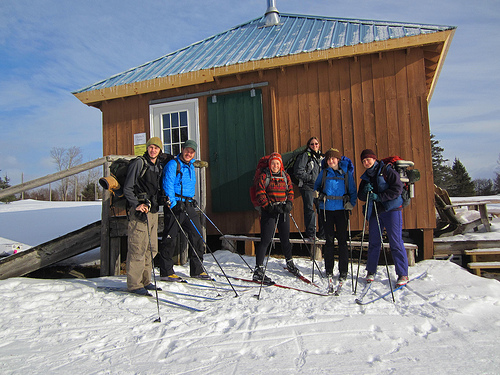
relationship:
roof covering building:
[71, 0, 457, 104] [72, 0, 457, 276]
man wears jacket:
[123, 136, 169, 296] [115, 151, 167, 221]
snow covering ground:
[4, 199, 497, 373] [1, 194, 499, 373]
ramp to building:
[7, 220, 90, 293] [76, 12, 468, 264]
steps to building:
[448, 233, 482, 272] [76, 12, 468, 264]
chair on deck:
[434, 184, 482, 231] [443, 230, 484, 257]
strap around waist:
[318, 196, 348, 202] [320, 180, 347, 215]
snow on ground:
[0, 196, 499, 374] [180, 325, 290, 375]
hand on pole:
[275, 206, 285, 217] [258, 205, 308, 286]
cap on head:
[362, 148, 374, 157] [361, 150, 373, 165]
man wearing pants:
[108, 149, 174, 298] [124, 202, 164, 300]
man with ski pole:
[123, 136, 169, 296] [144, 213, 162, 322]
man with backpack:
[123, 136, 169, 296] [100, 147, 133, 202]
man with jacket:
[160, 138, 212, 279] [163, 153, 195, 209]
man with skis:
[357, 148, 409, 286] [251, 237, 414, 303]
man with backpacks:
[357, 148, 409, 286] [252, 138, 422, 196]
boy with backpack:
[252, 153, 300, 285] [252, 160, 273, 200]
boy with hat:
[252, 153, 300, 285] [267, 151, 284, 162]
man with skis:
[123, 136, 169, 296] [142, 258, 402, 306]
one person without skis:
[293, 129, 321, 220] [142, 258, 402, 306]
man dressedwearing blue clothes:
[357, 148, 409, 286] [364, 172, 402, 251]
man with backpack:
[357, 148, 409, 286] [380, 151, 414, 194]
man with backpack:
[357, 148, 409, 286] [378, 153, 420, 187]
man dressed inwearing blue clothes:
[357, 148, 409, 286] [360, 170, 406, 253]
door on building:
[146, 106, 198, 154] [76, 0, 451, 248]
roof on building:
[60, 0, 450, 107] [76, 0, 451, 248]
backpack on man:
[92, 160, 133, 190] [123, 136, 169, 296]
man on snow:
[123, 136, 169, 296] [190, 283, 440, 350]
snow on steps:
[470, 245, 486, 264] [466, 240, 493, 279]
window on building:
[147, 95, 191, 148] [116, 49, 426, 234]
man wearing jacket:
[160, 138, 212, 279] [167, 156, 207, 199]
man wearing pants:
[160, 138, 212, 279] [178, 212, 219, 262]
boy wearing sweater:
[246, 148, 310, 272] [266, 178, 293, 206]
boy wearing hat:
[252, 153, 300, 285] [262, 145, 288, 166]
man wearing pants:
[357, 148, 409, 286] [363, 210, 417, 270]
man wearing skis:
[357, 148, 409, 286] [346, 278, 423, 306]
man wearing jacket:
[123, 136, 169, 296] [124, 157, 167, 218]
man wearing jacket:
[123, 136, 169, 296] [123, 153, 167, 212]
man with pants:
[123, 136, 169, 296] [127, 208, 157, 298]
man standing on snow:
[160, 138, 212, 279] [7, 251, 497, 371]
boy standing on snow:
[252, 153, 300, 285] [7, 251, 497, 371]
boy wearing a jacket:
[252, 153, 300, 285] [256, 169, 294, 207]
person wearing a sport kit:
[315, 149, 354, 274] [310, 149, 360, 301]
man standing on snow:
[357, 148, 417, 288] [7, 251, 497, 371]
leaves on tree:
[450, 157, 470, 192] [450, 156, 469, 191]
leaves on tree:
[81, 180, 97, 194] [79, 176, 98, 199]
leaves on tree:
[453, 168, 470, 186] [449, 160, 471, 195]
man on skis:
[123, 136, 169, 296] [70, 269, 212, 309]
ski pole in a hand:
[139, 213, 163, 324] [132, 205, 152, 216]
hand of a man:
[132, 205, 152, 216] [123, 136, 169, 296]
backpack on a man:
[106, 156, 133, 207] [128, 138, 168, 296]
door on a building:
[200, 82, 277, 218] [72, 0, 457, 276]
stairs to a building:
[466, 241, 497, 284] [72, 0, 457, 276]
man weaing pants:
[357, 148, 409, 286] [368, 200, 410, 279]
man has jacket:
[160, 138, 212, 279] [161, 155, 200, 208]